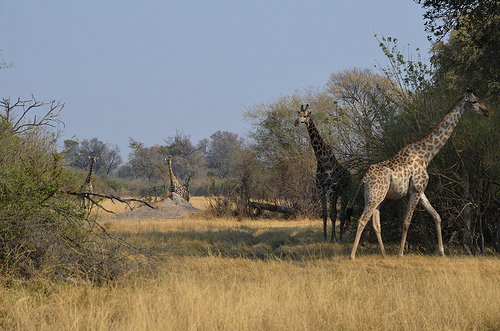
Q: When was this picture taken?
A: During the day.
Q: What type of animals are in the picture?
A: Giraffes.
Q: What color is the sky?
A: Blue.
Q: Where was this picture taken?
A: In a field.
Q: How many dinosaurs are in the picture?
A: Zero.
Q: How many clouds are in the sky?
A: Zero.